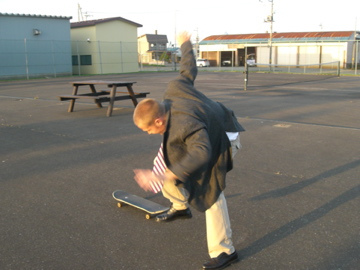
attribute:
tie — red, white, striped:
[150, 140, 169, 194]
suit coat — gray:
[161, 39, 245, 212]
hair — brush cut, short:
[132, 99, 166, 128]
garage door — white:
[321, 44, 348, 70]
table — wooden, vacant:
[59, 79, 151, 119]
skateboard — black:
[110, 188, 171, 221]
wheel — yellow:
[117, 202, 123, 209]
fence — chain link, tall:
[1, 37, 359, 80]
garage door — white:
[298, 42, 322, 68]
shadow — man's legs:
[234, 158, 359, 261]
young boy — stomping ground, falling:
[132, 30, 246, 269]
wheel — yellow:
[145, 212, 151, 221]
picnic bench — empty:
[59, 95, 113, 119]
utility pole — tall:
[264, 0, 276, 72]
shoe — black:
[154, 206, 194, 224]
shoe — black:
[202, 250, 239, 270]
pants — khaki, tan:
[161, 133, 242, 259]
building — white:
[198, 30, 359, 73]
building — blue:
[1, 15, 74, 79]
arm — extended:
[178, 33, 198, 88]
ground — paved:
[1, 71, 360, 269]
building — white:
[138, 32, 178, 69]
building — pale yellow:
[71, 16, 143, 75]